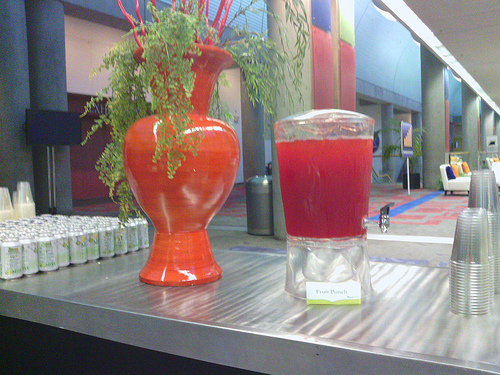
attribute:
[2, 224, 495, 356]
counter — silver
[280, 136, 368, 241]
liquid — red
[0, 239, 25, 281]
soda cans — row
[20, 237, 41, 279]
soda cans — row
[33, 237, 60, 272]
soda cans — row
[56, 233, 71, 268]
soda cans — row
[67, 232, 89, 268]
soda cans — row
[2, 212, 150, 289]
cans — large amount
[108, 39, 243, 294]
vase — large, orange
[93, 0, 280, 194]
plant — potted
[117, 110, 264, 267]
vase — orange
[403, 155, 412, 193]
pole — metal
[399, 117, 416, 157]
sign — blue, yellow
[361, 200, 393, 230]
spout — juice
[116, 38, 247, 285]
vase — large, shiny, orange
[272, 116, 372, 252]
drink — red